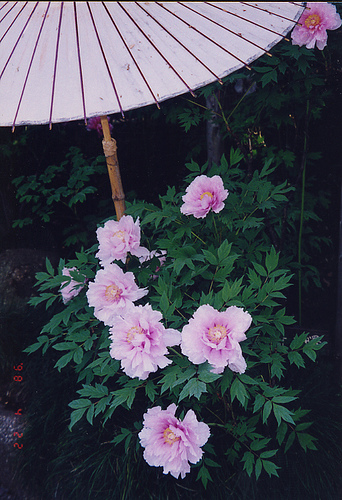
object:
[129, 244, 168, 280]
flower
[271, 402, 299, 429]
green leaves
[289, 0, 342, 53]
flower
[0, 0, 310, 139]
umbrella brim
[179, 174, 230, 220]
flower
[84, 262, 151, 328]
flower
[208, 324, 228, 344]
yellow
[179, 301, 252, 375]
flower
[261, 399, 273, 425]
green leaves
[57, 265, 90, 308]
flowers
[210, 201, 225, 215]
petal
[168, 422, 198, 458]
petals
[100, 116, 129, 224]
stick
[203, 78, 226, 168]
trunk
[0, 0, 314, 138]
umbrella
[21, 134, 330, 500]
tree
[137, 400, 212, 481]
flower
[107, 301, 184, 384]
flower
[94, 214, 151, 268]
flower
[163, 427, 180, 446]
center